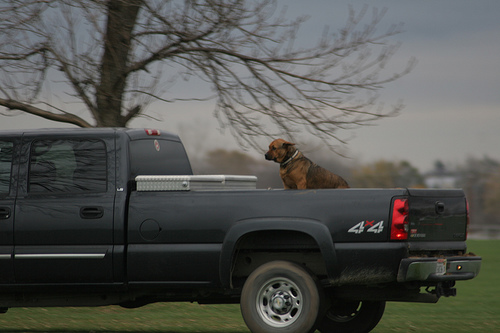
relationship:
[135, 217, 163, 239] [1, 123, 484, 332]
cover on side of truck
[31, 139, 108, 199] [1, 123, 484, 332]
windows on truck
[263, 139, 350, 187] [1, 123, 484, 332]
dog in truck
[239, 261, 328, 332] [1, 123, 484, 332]
wheel on truck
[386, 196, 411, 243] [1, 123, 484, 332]
light on truck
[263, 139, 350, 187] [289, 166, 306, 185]
dog fur brown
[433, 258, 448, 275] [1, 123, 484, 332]
plate on truck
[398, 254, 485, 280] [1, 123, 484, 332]
bumper of truck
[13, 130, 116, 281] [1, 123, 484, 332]
door of truck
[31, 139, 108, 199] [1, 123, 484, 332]
window of truck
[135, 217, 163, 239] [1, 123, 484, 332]
cover on truck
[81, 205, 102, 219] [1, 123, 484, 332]
handle on truck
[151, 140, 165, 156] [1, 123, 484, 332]
sticker on truck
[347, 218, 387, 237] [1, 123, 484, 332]
sign on truck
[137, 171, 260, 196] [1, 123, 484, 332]
box in truck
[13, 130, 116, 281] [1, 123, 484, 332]
door on truck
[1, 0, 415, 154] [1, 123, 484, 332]
tree by truck